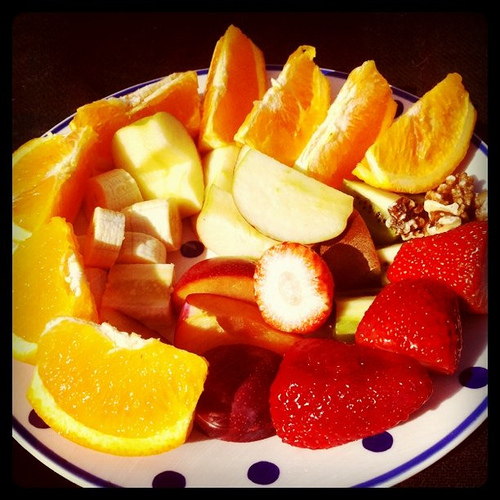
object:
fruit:
[29, 317, 208, 465]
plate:
[8, 65, 489, 487]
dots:
[247, 461, 278, 486]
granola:
[424, 199, 459, 214]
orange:
[194, 25, 266, 151]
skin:
[227, 349, 279, 442]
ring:
[0, 63, 497, 488]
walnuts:
[382, 168, 486, 242]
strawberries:
[269, 336, 435, 448]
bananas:
[117, 198, 182, 253]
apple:
[231, 142, 354, 243]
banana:
[82, 206, 126, 268]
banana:
[115, 230, 166, 264]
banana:
[88, 167, 146, 211]